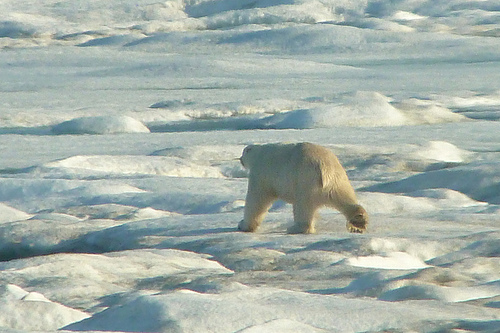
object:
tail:
[319, 163, 330, 189]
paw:
[286, 225, 313, 234]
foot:
[343, 207, 368, 234]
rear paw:
[344, 215, 367, 234]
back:
[253, 140, 334, 162]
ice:
[377, 22, 492, 62]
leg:
[241, 185, 271, 225]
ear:
[243, 143, 252, 153]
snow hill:
[73, 30, 149, 49]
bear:
[237, 142, 368, 235]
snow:
[192, 22, 378, 57]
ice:
[110, 284, 245, 332]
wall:
[0, 10, 51, 39]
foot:
[284, 220, 317, 234]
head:
[237, 144, 254, 168]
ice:
[38, 77, 147, 110]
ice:
[125, 35, 277, 102]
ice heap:
[38, 153, 226, 182]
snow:
[382, 187, 490, 217]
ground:
[89, 238, 222, 285]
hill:
[52, 111, 149, 134]